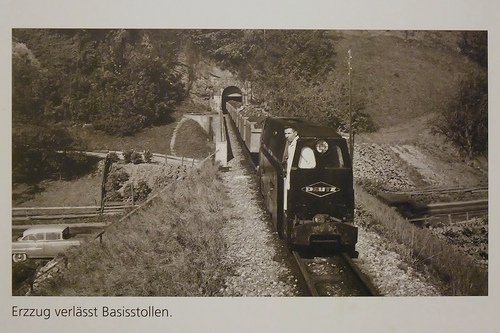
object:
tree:
[423, 62, 495, 166]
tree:
[0, 150, 86, 178]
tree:
[55, 48, 177, 118]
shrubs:
[378, 178, 427, 276]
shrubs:
[144, 160, 226, 272]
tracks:
[274, 239, 394, 301]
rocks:
[242, 232, 270, 261]